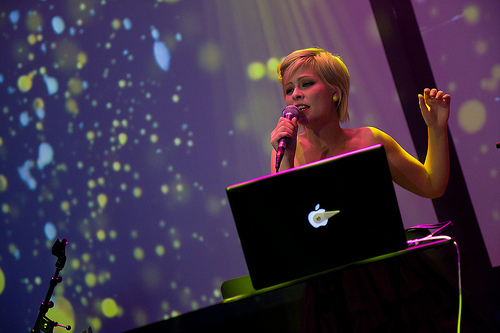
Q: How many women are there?
A: One.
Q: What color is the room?
A: Purple and pink.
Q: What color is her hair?
A: Blonde.